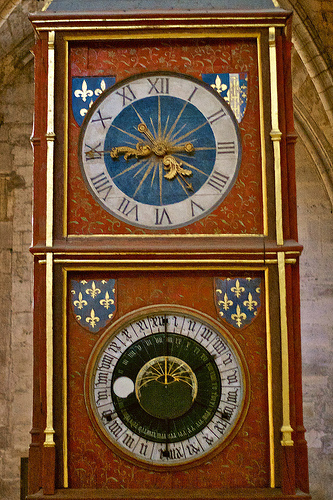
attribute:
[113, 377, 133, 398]
circle — white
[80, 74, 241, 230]
clock face — black circle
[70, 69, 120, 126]
shield — colorful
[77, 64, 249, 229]
clock — decorative blue crest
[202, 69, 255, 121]
crest — blue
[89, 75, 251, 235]
face — clock